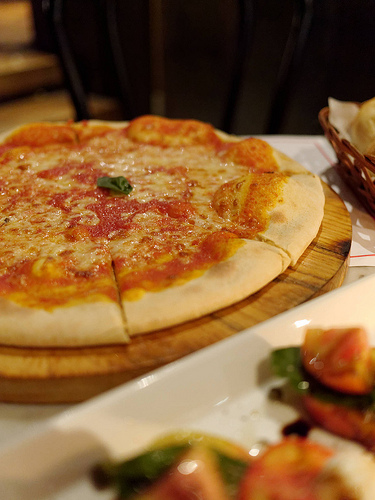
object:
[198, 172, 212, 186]
cheese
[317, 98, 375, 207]
basket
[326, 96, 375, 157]
bread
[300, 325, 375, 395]
food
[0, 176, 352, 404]
platter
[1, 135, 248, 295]
cheese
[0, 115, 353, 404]
tray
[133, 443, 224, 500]
tomatoes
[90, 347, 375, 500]
basil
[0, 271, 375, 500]
tray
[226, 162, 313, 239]
crust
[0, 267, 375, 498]
serving tray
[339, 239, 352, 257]
circle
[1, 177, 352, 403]
wood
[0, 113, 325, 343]
food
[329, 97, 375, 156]
napkin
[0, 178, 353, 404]
cutting board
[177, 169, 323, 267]
cheese pizza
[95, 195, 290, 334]
slice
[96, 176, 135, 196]
sprig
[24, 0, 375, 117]
backrest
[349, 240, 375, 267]
napkin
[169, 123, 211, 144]
cheese pizza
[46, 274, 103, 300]
cheese pizza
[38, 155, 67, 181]
cheese pizza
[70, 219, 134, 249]
cheese pizza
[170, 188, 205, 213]
cheese pizza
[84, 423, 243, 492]
lettuce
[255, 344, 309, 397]
lettuce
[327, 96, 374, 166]
rolls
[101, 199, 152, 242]
sauce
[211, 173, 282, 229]
air pockets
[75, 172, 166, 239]
sauce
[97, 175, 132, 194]
vegetable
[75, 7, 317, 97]
rungs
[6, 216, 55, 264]
cheese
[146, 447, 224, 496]
sliced appetizers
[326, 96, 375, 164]
food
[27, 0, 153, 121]
stairs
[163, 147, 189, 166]
cheese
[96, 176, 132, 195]
lettuce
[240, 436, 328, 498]
tomatoe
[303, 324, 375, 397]
tomatoe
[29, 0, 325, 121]
chair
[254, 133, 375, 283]
table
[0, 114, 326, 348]
pizza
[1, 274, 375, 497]
plate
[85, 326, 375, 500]
appetizers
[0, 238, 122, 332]
crust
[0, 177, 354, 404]
board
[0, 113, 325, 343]
pizza toppings